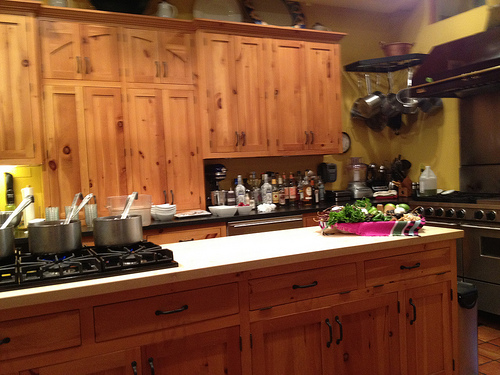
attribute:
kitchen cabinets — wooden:
[0, 238, 459, 373]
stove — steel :
[436, 187, 498, 330]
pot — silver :
[2, 209, 18, 261]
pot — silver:
[0, 188, 32, 249]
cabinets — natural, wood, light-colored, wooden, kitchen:
[2, 2, 344, 229]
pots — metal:
[354, 82, 446, 120]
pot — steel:
[93, 215, 143, 247]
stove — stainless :
[405, 190, 499, 320]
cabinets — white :
[31, 187, 495, 371]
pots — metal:
[345, 84, 454, 134]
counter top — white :
[9, 210, 469, 373]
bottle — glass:
[236, 173, 248, 208]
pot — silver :
[91, 213, 144, 246]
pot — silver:
[24, 217, 84, 254]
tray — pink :
[320, 221, 424, 235]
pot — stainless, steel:
[28, 190, 94, 259]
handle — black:
[154, 300, 189, 318]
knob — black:
[455, 206, 466, 219]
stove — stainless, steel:
[396, 185, 497, 321]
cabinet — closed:
[124, 81, 168, 213]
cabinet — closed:
[196, 27, 246, 156]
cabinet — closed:
[265, 31, 309, 156]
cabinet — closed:
[42, 76, 87, 223]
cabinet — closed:
[124, 26, 191, 89]